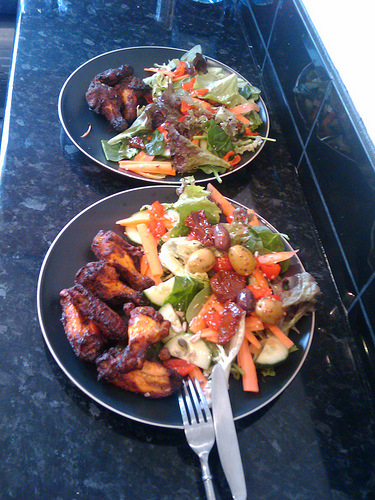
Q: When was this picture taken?
A: Daytime.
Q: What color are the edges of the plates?
A: White.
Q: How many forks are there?
A: One.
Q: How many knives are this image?
A: One.